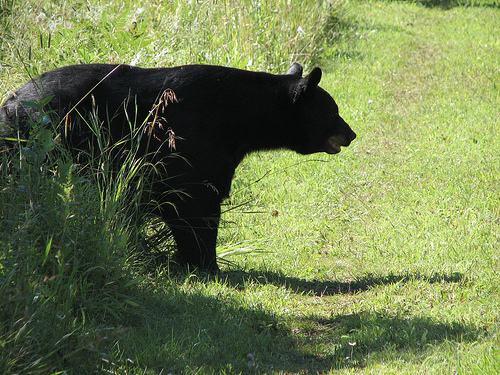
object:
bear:
[1, 61, 358, 271]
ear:
[286, 62, 303, 76]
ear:
[304, 68, 323, 88]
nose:
[351, 131, 356, 140]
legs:
[152, 206, 221, 273]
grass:
[74, 106, 97, 137]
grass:
[230, 159, 331, 199]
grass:
[220, 198, 254, 212]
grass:
[132, 95, 139, 127]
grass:
[1, 135, 29, 143]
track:
[320, 14, 440, 316]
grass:
[0, 0, 89, 53]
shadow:
[147, 251, 465, 297]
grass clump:
[1, 289, 125, 324]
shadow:
[2, 299, 490, 374]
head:
[284, 62, 358, 155]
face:
[318, 87, 358, 155]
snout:
[325, 115, 357, 154]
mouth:
[328, 133, 349, 151]